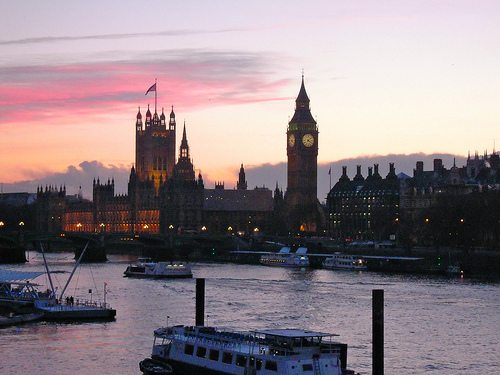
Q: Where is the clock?
A: On the tower.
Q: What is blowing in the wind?
A: A flag.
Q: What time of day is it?
A: Sunset.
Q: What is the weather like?
A: Clear.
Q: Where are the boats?
A: On water.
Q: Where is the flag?
A: At the top of the building.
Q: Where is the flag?
A: On top of the tall building.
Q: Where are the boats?
A: In the water.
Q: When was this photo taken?
A: At sunset.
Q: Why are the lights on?
A: It is a little dark outside.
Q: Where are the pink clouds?
A: On the horizon.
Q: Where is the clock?
A: On the tall tower.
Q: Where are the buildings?
A: Across the water.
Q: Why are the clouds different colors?
A: The sun is setting.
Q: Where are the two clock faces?
A: On the tall tower.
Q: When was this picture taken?
A: Evening.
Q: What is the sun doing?
A: Setting.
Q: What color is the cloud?
A: Pink.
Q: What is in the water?
A: Boats.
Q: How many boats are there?
A: Four.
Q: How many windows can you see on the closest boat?
A: Seven.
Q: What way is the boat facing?
A: Left.